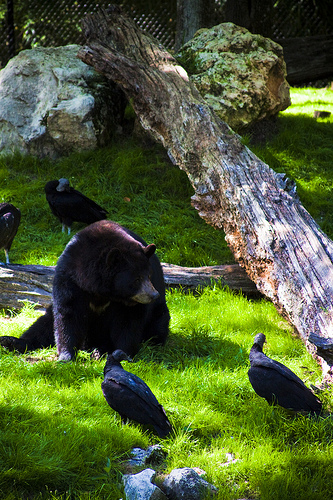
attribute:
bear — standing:
[0, 219, 173, 363]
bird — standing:
[247, 333, 325, 412]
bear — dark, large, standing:
[44, 214, 182, 366]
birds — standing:
[44, 178, 107, 233]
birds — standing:
[99, 347, 175, 438]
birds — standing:
[246, 332, 321, 414]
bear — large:
[63, 199, 171, 325]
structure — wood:
[0, 261, 54, 315]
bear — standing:
[45, 220, 191, 354]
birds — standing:
[85, 326, 330, 436]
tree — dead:
[0, 10, 332, 387]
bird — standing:
[91, 342, 177, 445]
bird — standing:
[232, 326, 329, 422]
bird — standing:
[98, 346, 182, 444]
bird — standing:
[240, 326, 328, 416]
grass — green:
[19, 386, 48, 416]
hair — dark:
[52, 219, 170, 366]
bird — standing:
[97, 347, 175, 442]